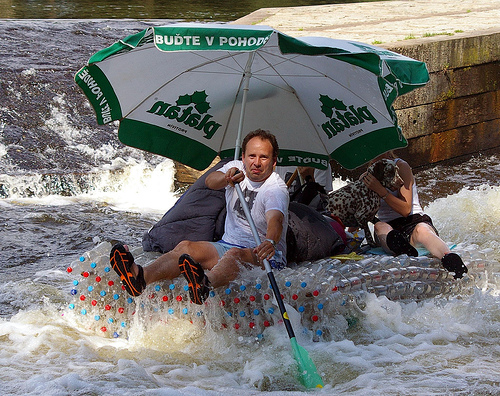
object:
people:
[106, 130, 466, 305]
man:
[108, 130, 292, 305]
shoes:
[108, 244, 212, 305]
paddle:
[266, 291, 334, 391]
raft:
[62, 227, 487, 342]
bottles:
[357, 277, 400, 294]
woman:
[360, 151, 468, 279]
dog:
[324, 158, 406, 249]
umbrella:
[74, 22, 431, 171]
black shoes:
[385, 229, 470, 279]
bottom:
[107, 244, 143, 297]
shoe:
[178, 252, 214, 305]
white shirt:
[216, 160, 289, 262]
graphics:
[231, 190, 256, 213]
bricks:
[372, 14, 500, 83]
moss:
[424, 60, 500, 132]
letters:
[317, 95, 378, 141]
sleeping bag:
[142, 186, 229, 253]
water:
[0, 138, 116, 235]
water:
[0, 1, 234, 20]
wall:
[370, 32, 500, 176]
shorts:
[211, 233, 287, 272]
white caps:
[387, 321, 473, 378]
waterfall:
[23, 92, 134, 220]